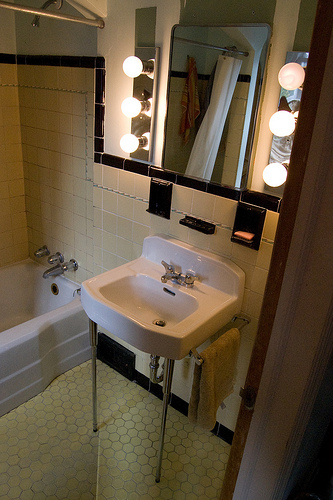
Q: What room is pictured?
A: It is a bathroom.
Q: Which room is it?
A: It is a bathroom.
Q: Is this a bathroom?
A: Yes, it is a bathroom.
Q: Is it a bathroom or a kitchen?
A: It is a bathroom.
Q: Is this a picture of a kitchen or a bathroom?
A: It is showing a bathroom.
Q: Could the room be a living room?
A: No, it is a bathroom.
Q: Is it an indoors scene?
A: Yes, it is indoors.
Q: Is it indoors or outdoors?
A: It is indoors.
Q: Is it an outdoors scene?
A: No, it is indoors.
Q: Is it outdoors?
A: No, it is indoors.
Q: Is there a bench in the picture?
A: No, there are no benches.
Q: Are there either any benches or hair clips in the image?
A: No, there are no benches or hair clips.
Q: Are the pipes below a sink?
A: Yes, the pipes are below a sink.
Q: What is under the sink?
A: The pipes are under the sink.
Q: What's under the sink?
A: The pipes are under the sink.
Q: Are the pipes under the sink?
A: Yes, the pipes are under the sink.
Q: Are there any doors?
A: Yes, there is a door.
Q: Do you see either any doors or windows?
A: Yes, there is a door.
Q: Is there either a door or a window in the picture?
A: Yes, there is a door.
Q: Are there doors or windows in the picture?
A: Yes, there is a door.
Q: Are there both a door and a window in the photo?
A: No, there is a door but no windows.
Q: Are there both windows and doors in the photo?
A: No, there is a door but no windows.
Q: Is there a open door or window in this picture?
A: Yes, there is an open door.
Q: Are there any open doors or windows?
A: Yes, there is an open door.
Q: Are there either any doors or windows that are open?
A: Yes, the door is open.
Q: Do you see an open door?
A: Yes, there is an open door.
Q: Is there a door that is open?
A: Yes, there is a door that is open.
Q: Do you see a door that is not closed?
A: Yes, there is a open door.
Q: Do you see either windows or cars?
A: No, there are no cars or windows.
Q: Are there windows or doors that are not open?
A: No, there is a door but it is open.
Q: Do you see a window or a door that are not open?
A: No, there is a door but it is open.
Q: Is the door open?
A: Yes, the door is open.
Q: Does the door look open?
A: Yes, the door is open.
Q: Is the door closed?
A: No, the door is open.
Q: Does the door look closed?
A: No, the door is open.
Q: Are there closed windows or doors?
A: No, there is a door but it is open.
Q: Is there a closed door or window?
A: No, there is a door but it is open.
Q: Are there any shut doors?
A: No, there is a door but it is open.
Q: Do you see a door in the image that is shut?
A: No, there is a door but it is open.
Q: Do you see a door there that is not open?
A: No, there is a door but it is open.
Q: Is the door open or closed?
A: The door is open.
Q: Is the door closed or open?
A: The door is open.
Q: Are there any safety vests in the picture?
A: No, there are no safety vests.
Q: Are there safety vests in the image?
A: No, there are no safety vests.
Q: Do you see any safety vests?
A: No, there are no safety vests.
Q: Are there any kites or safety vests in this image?
A: No, there are no safety vests or kites.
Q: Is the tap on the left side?
A: Yes, the tap is on the left of the image.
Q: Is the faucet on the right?
A: No, the faucet is on the left of the image.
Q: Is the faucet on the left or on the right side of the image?
A: The faucet is on the left of the image.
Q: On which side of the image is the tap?
A: The tap is on the left of the image.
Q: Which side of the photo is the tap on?
A: The tap is on the left of the image.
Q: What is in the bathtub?
A: The faucet is in the bathtub.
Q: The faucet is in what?
A: The faucet is in the bathtub.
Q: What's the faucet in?
A: The faucet is in the bathtub.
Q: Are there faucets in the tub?
A: Yes, there is a faucet in the tub.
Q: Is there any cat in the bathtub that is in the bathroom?
A: No, there is a faucet in the bathtub.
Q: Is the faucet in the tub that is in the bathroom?
A: Yes, the faucet is in the bathtub.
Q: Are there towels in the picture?
A: Yes, there is a towel.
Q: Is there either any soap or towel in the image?
A: Yes, there is a towel.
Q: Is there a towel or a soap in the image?
A: Yes, there is a towel.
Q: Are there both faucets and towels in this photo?
A: Yes, there are both a towel and a faucet.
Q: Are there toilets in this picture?
A: No, there are no toilets.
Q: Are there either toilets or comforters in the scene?
A: No, there are no toilets or comforters.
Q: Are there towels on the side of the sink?
A: Yes, there is a towel on the side of the sink.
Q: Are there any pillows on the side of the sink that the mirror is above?
A: No, there is a towel on the side of the sink.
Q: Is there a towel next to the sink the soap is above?
A: Yes, there is a towel next to the sink.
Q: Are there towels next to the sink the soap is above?
A: Yes, there is a towel next to the sink.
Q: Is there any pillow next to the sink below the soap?
A: No, there is a towel next to the sink.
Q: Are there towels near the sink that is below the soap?
A: Yes, there is a towel near the sink.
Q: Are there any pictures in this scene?
A: No, there are no pictures.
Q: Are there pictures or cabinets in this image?
A: No, there are no pictures or cabinets.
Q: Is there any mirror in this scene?
A: Yes, there is a mirror.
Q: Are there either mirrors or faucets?
A: Yes, there is a mirror.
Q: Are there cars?
A: No, there are no cars.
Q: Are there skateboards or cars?
A: No, there are no cars or skateboards.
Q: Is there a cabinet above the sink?
A: No, there is a mirror above the sink.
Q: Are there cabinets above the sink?
A: No, there is a mirror above the sink.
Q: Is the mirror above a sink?
A: Yes, the mirror is above a sink.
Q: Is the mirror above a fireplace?
A: No, the mirror is above a sink.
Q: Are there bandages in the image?
A: No, there are no bandages.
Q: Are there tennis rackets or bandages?
A: No, there are no bandages or tennis rackets.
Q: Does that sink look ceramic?
A: Yes, the sink is ceramic.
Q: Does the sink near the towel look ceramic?
A: Yes, the sink is ceramic.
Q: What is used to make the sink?
A: The sink is made of porcelain.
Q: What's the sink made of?
A: The sink is made of porcelain.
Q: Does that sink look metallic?
A: No, the sink is ceramic.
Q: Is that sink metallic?
A: No, the sink is ceramic.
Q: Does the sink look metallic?
A: No, the sink is ceramic.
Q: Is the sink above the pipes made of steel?
A: No, the sink is made of porcelain.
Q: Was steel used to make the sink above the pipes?
A: No, the sink is made of porcelain.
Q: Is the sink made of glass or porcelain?
A: The sink is made of porcelain.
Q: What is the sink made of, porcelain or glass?
A: The sink is made of porcelain.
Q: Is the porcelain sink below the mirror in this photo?
A: Yes, the sink is below the mirror.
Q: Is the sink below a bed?
A: No, the sink is below the mirror.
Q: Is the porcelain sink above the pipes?
A: Yes, the sink is above the pipes.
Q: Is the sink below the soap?
A: Yes, the sink is below the soap.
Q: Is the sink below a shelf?
A: No, the sink is below the soap.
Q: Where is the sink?
A: The sink is in the bathroom.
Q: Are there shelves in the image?
A: No, there are no shelves.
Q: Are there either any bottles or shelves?
A: No, there are no shelves or bottles.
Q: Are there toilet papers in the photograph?
A: No, there are no toilet papers.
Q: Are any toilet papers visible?
A: No, there are no toilet papers.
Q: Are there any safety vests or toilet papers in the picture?
A: No, there are no toilet papers or safety vests.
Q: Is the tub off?
A: Yes, the tub is off.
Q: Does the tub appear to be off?
A: Yes, the tub is off.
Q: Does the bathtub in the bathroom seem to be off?
A: Yes, the bathtub is off.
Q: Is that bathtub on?
A: No, the bathtub is off.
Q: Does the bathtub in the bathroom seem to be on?
A: No, the bathtub is off.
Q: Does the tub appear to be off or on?
A: The tub is off.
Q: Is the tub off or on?
A: The tub is off.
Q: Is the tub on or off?
A: The tub is off.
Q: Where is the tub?
A: The tub is in the bathroom.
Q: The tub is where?
A: The tub is in the bathroom.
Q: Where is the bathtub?
A: The tub is in the bathroom.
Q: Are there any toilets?
A: No, there are no toilets.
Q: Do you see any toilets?
A: No, there are no toilets.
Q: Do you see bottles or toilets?
A: No, there are no toilets or bottles.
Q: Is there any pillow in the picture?
A: No, there are no pillows.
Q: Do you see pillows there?
A: No, there are no pillows.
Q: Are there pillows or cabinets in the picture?
A: No, there are no pillows or cabinets.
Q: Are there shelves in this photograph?
A: No, there are no shelves.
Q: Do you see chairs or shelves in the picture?
A: No, there are no shelves or chairs.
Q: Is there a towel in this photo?
A: Yes, there is a towel.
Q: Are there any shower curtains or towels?
A: Yes, there is a towel.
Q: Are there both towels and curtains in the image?
A: Yes, there are both a towel and a curtain.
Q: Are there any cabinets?
A: No, there are no cabinets.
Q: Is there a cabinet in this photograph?
A: No, there are no cabinets.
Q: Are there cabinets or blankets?
A: No, there are no cabinets or blankets.